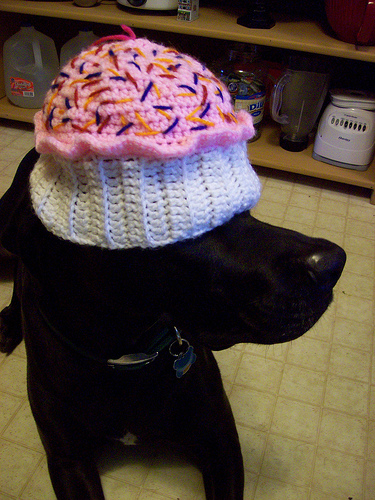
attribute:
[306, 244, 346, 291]
nose — black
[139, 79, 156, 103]
yarn — blue, pink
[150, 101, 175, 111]
sprinkle — stitched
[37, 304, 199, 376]
collar — blue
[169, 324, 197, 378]
tag — is blue, is metal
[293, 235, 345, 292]
nose — black, shiny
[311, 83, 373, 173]
blender — white, under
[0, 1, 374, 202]
shelf — wooden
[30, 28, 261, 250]
yarn — red, pink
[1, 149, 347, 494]
dog — is black, black, wearing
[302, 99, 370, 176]
base — white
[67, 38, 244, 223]
hat — ugly, crochet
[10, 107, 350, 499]
dog — black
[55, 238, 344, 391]
dog — black, wearing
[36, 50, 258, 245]
hat — pink, white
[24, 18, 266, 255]
hat — white, red, blue, pink, knitted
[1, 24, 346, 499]
dog — white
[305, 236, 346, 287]
nose — black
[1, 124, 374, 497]
floor — tan, tiled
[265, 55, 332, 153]
pitcher — plastic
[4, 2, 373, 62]
shelf — wooden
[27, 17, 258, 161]
crocheted hat — is crocheted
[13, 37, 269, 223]
beanie — knitted, pink and white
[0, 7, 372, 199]
shelving — wooden, light tan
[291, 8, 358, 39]
containre — red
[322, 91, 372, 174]
white can — bent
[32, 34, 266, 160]
yarn — pink, red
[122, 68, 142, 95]
yarn — red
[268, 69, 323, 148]
object — green 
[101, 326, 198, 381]
collar — blue